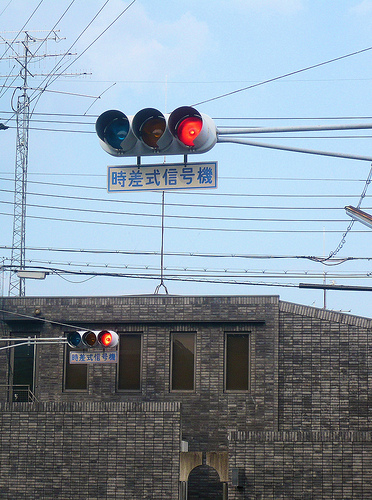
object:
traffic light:
[93, 108, 219, 156]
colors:
[104, 117, 129, 148]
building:
[0, 294, 372, 500]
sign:
[105, 160, 218, 194]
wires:
[0, 0, 44, 62]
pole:
[213, 122, 372, 136]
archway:
[179, 450, 229, 500]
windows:
[218, 329, 254, 395]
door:
[12, 335, 38, 403]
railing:
[0, 382, 41, 404]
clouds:
[346, 0, 372, 19]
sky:
[0, 0, 372, 326]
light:
[34, 307, 42, 317]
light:
[167, 105, 209, 149]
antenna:
[8, 28, 36, 298]